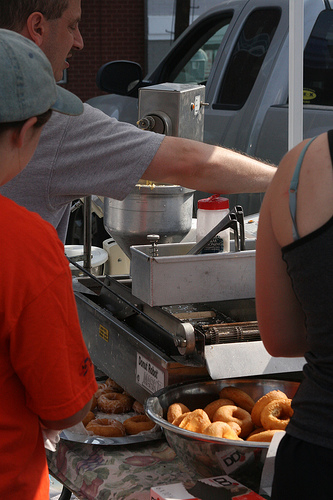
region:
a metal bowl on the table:
[143, 376, 296, 484]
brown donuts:
[165, 388, 293, 444]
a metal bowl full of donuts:
[142, 375, 300, 473]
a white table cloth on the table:
[80, 450, 177, 479]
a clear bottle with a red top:
[195, 194, 230, 251]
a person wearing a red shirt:
[0, 28, 96, 499]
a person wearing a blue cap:
[0, 27, 98, 497]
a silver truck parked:
[84, 2, 331, 138]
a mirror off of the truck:
[96, 60, 142, 95]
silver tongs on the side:
[190, 204, 247, 251]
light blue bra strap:
[288, 136, 318, 237]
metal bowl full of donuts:
[148, 378, 296, 469]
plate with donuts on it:
[82, 376, 154, 444]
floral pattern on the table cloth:
[44, 441, 186, 499]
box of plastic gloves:
[150, 475, 256, 499]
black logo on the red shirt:
[78, 357, 91, 379]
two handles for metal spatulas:
[188, 203, 246, 255]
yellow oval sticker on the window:
[302, 90, 315, 99]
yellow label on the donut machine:
[99, 326, 108, 342]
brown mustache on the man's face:
[66, 47, 77, 55]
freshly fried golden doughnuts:
[135, 369, 301, 461]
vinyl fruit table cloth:
[54, 429, 204, 498]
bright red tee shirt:
[0, 189, 103, 493]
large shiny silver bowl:
[145, 374, 310, 494]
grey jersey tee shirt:
[1, 88, 165, 226]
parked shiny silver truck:
[67, 0, 332, 218]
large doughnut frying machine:
[71, 77, 287, 416]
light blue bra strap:
[282, 128, 320, 243]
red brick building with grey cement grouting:
[56, 4, 151, 102]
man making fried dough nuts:
[0, 1, 304, 260]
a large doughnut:
[262, 398, 293, 429]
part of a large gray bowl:
[145, 376, 298, 474]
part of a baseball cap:
[0, 28, 86, 123]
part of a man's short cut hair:
[0, 0, 66, 37]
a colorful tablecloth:
[50, 444, 187, 498]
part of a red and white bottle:
[190, 189, 233, 245]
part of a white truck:
[82, 0, 331, 169]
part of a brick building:
[83, 1, 145, 65]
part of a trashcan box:
[149, 470, 265, 499]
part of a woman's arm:
[252, 153, 308, 360]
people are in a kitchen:
[4, 9, 331, 497]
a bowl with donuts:
[138, 375, 289, 479]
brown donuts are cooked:
[137, 372, 303, 481]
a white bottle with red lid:
[188, 187, 233, 253]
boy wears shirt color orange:
[1, 26, 100, 497]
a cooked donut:
[86, 412, 125, 442]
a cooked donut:
[93, 388, 132, 414]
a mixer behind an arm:
[97, 72, 210, 235]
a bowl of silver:
[99, 179, 199, 267]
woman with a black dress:
[245, 119, 331, 496]